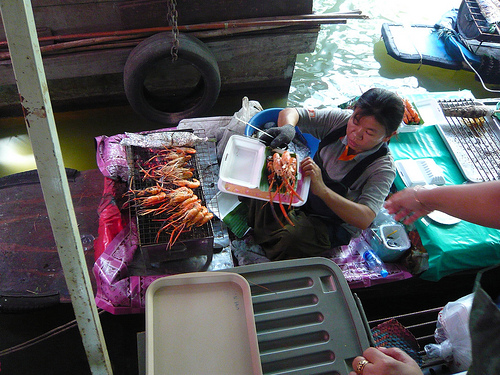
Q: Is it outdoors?
A: Yes, it is outdoors.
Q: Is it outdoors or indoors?
A: It is outdoors.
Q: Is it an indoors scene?
A: No, it is outdoors.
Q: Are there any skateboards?
A: No, there are no skateboards.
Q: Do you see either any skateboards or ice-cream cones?
A: No, there are no skateboards or ice-cream cones.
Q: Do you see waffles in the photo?
A: No, there are no waffles.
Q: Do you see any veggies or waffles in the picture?
A: No, there are no waffles or veggies.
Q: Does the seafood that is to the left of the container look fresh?
A: Yes, the seafood is fresh.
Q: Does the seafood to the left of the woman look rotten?
A: No, the seafood is fresh.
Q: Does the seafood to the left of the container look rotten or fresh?
A: The seafood is fresh.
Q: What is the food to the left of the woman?
A: The food is seafood.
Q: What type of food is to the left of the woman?
A: The food is seafood.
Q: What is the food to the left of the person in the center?
A: The food is seafood.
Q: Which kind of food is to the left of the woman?
A: The food is seafood.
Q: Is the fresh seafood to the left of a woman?
A: Yes, the seafood is to the left of a woman.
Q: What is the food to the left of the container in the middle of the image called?
A: The food is seafood.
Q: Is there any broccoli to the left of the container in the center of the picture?
A: No, there is seafood to the left of the container.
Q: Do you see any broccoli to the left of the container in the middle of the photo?
A: No, there is seafood to the left of the container.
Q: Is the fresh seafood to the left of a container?
A: Yes, the seafood is to the left of a container.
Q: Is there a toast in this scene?
A: No, there are no toasts.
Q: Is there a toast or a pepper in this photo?
A: No, there are no toasts or peppers.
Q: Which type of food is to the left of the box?
A: The food is seafood.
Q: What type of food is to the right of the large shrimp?
A: The food is seafood.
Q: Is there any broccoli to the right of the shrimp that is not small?
A: No, there is seafood to the right of the shrimp.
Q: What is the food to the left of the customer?
A: The food is seafood.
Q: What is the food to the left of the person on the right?
A: The food is seafood.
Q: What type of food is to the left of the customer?
A: The food is seafood.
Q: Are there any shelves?
A: No, there are no shelves.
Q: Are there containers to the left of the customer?
A: Yes, there is a container to the left of the customer.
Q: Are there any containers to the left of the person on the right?
A: Yes, there is a container to the left of the customer.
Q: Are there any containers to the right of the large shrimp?
A: Yes, there is a container to the right of the shrimp.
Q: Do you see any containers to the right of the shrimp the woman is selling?
A: Yes, there is a container to the right of the shrimp.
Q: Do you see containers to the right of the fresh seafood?
A: Yes, there is a container to the right of the seafood.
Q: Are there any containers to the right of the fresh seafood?
A: Yes, there is a container to the right of the seafood.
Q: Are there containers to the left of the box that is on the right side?
A: Yes, there is a container to the left of the box.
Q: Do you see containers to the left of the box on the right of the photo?
A: Yes, there is a container to the left of the box.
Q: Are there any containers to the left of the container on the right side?
A: Yes, there is a container to the left of the box.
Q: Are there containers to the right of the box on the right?
A: No, the container is to the left of the box.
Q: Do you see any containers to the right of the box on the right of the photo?
A: No, the container is to the left of the box.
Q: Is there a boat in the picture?
A: Yes, there is a boat.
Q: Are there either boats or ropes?
A: Yes, there is a boat.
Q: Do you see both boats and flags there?
A: No, there is a boat but no flags.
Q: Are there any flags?
A: No, there are no flags.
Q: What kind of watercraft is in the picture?
A: The watercraft is a boat.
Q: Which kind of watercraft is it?
A: The watercraft is a boat.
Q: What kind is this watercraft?
A: This is a boat.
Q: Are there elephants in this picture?
A: No, there are no elephants.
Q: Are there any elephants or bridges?
A: No, there are no elephants or bridges.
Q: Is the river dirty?
A: Yes, the river is dirty.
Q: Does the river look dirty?
A: Yes, the river is dirty.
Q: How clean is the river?
A: The river is dirty.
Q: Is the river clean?
A: No, the river is dirty.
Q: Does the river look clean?
A: No, the river is dirty.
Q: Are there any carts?
A: No, there are no carts.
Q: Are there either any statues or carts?
A: No, there are no carts or statues.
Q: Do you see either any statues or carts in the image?
A: No, there are no carts or statues.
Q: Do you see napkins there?
A: No, there are no napkins.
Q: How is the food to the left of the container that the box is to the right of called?
A: The food is shrimp.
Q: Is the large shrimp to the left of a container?
A: Yes, the shrimp is to the left of a container.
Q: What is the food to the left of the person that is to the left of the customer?
A: The food is shrimp.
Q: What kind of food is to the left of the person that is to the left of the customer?
A: The food is shrimp.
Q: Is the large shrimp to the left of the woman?
A: Yes, the shrimp is to the left of the woman.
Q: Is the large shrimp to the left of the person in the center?
A: Yes, the shrimp is to the left of the woman.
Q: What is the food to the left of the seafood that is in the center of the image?
A: The food is shrimp.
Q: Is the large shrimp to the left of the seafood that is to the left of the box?
A: Yes, the shrimp is to the left of the seafood.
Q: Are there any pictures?
A: No, there are no pictures.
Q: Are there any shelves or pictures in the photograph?
A: No, there are no pictures or shelves.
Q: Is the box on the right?
A: Yes, the box is on the right of the image.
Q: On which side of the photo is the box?
A: The box is on the right of the image.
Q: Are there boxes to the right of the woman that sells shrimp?
A: Yes, there is a box to the right of the woman.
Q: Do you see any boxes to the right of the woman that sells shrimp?
A: Yes, there is a box to the right of the woman.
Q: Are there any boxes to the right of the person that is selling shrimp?
A: Yes, there is a box to the right of the woman.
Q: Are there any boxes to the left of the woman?
A: No, the box is to the right of the woman.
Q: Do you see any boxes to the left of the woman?
A: No, the box is to the right of the woman.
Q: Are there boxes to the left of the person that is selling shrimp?
A: No, the box is to the right of the woman.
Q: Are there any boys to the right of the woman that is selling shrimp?
A: No, there is a box to the right of the woman.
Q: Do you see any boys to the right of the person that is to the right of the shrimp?
A: No, there is a box to the right of the woman.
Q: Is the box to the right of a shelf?
A: No, the box is to the right of a woman.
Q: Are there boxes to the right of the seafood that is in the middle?
A: Yes, there is a box to the right of the seafood.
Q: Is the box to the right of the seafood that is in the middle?
A: Yes, the box is to the right of the seafood.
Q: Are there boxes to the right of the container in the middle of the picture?
A: Yes, there is a box to the right of the container.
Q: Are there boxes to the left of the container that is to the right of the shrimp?
A: No, the box is to the right of the container.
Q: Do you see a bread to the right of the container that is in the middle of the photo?
A: No, there is a box to the right of the container.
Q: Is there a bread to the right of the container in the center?
A: No, there is a box to the right of the container.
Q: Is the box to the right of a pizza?
A: No, the box is to the right of a container.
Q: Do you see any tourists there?
A: No, there are no tourists.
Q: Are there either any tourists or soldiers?
A: No, there are no tourists or soldiers.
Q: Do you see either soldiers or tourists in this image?
A: No, there are no tourists or soldiers.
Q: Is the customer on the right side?
A: Yes, the customer is on the right of the image.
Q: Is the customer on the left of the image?
A: No, the customer is on the right of the image.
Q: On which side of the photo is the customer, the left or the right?
A: The customer is on the right of the image.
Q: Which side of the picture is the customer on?
A: The customer is on the right of the image.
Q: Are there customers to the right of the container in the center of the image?
A: Yes, there is a customer to the right of the container.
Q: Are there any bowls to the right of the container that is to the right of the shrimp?
A: No, there is a customer to the right of the container.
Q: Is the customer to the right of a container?
A: Yes, the customer is to the right of a container.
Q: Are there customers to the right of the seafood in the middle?
A: Yes, there is a customer to the right of the seafood.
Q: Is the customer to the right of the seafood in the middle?
A: Yes, the customer is to the right of the seafood.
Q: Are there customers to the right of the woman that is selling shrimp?
A: Yes, there is a customer to the right of the woman.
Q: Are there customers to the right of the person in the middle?
A: Yes, there is a customer to the right of the woman.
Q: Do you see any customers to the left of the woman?
A: No, the customer is to the right of the woman.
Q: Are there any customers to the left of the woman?
A: No, the customer is to the right of the woman.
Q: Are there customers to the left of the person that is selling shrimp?
A: No, the customer is to the right of the woman.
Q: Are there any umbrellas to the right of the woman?
A: No, there is a customer to the right of the woman.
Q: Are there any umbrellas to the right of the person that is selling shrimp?
A: No, there is a customer to the right of the woman.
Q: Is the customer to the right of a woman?
A: Yes, the customer is to the right of a woman.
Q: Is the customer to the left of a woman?
A: No, the customer is to the right of a woman.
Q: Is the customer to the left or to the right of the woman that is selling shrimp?
A: The customer is to the right of the woman.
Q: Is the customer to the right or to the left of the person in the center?
A: The customer is to the right of the woman.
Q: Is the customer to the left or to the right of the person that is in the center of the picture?
A: The customer is to the right of the woman.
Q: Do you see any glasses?
A: No, there are no glasses.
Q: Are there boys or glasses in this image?
A: No, there are no glasses or boys.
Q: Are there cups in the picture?
A: No, there are no cups.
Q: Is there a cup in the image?
A: No, there are no cups.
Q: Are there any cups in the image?
A: No, there are no cups.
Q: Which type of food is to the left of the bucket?
A: The food is shrimp.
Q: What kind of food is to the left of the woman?
A: The food is shrimp.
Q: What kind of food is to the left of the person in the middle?
A: The food is shrimp.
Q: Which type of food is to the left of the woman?
A: The food is shrimp.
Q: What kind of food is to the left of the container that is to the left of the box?
A: The food is shrimp.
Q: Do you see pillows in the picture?
A: No, there are no pillows.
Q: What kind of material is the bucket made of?
A: The bucket is made of plastic.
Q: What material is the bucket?
A: The bucket is made of plastic.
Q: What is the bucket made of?
A: The bucket is made of plastic.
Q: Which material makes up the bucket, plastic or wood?
A: The bucket is made of plastic.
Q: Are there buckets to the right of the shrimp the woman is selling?
A: Yes, there is a bucket to the right of the shrimp.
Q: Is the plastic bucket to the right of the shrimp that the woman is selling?
A: Yes, the bucket is to the right of the shrimp.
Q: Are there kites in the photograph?
A: No, there are no kites.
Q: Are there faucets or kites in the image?
A: No, there are no kites or faucets.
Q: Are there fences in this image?
A: No, there are no fences.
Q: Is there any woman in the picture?
A: Yes, there is a woman.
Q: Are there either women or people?
A: Yes, there is a woman.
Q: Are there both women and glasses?
A: No, there is a woman but no glasses.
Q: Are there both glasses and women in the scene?
A: No, there is a woman but no glasses.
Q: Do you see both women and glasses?
A: No, there is a woman but no glasses.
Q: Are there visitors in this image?
A: No, there are no visitors.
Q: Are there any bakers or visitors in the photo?
A: No, there are no visitors or bakers.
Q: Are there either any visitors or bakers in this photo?
A: No, there are no visitors or bakers.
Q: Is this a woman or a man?
A: This is a woman.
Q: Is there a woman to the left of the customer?
A: Yes, there is a woman to the left of the customer.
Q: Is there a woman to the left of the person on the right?
A: Yes, there is a woman to the left of the customer.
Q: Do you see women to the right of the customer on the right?
A: No, the woman is to the left of the customer.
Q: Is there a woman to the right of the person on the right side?
A: No, the woman is to the left of the customer.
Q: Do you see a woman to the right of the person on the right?
A: No, the woman is to the left of the customer.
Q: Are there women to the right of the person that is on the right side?
A: No, the woman is to the left of the customer.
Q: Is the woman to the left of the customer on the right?
A: Yes, the woman is to the left of the customer.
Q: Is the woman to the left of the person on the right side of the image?
A: Yes, the woman is to the left of the customer.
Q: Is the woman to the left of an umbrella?
A: No, the woman is to the left of the customer.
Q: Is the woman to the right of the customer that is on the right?
A: No, the woman is to the left of the customer.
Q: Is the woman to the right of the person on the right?
A: No, the woman is to the left of the customer.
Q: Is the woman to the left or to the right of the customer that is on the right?
A: The woman is to the left of the customer.